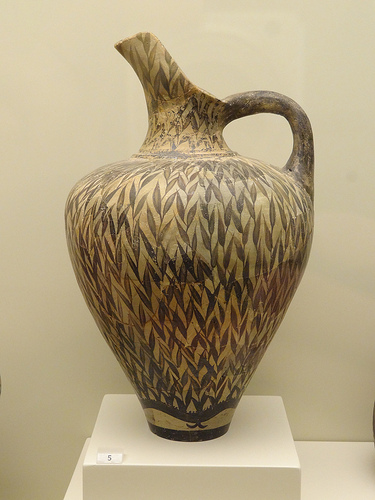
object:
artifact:
[64, 30, 317, 442]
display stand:
[82, 391, 301, 500]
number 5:
[107, 454, 111, 461]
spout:
[113, 28, 148, 100]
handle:
[221, 90, 315, 200]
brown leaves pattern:
[162, 189, 177, 222]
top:
[114, 29, 166, 47]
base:
[147, 420, 232, 442]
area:
[293, 440, 375, 500]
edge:
[281, 396, 302, 468]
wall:
[0, 0, 375, 500]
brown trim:
[142, 399, 239, 429]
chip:
[114, 31, 144, 49]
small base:
[150, 431, 229, 443]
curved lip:
[145, 28, 225, 105]